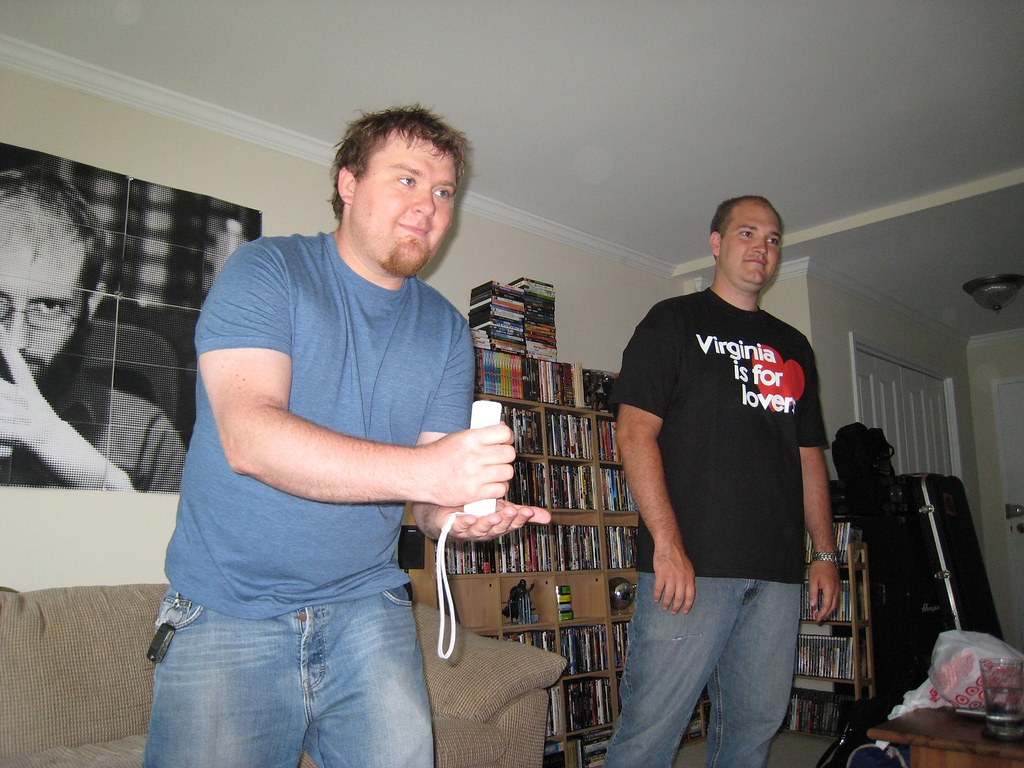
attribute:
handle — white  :
[433, 511, 468, 658]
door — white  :
[850, 340, 971, 483]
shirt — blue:
[231, 209, 899, 693]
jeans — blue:
[134, 592, 420, 740]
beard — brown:
[370, 242, 446, 281]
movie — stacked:
[532, 505, 613, 586]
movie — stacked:
[555, 499, 622, 610]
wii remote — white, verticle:
[459, 399, 511, 525]